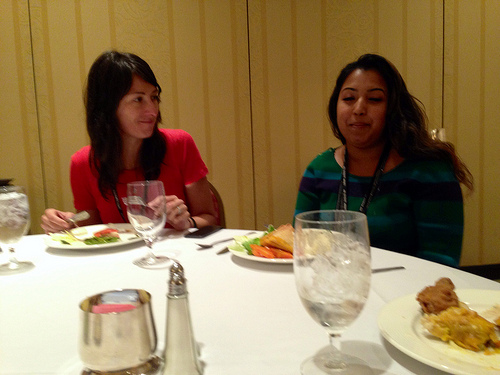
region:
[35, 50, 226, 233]
a woman in a red shirt sitting at a table.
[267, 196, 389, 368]
a glass filled with ice and liquid.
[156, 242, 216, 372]
a very tall salt shaker.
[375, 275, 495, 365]
a white plate with food on it.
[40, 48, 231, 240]
a woman sitting at a table.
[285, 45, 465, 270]
a woman sitting at a table with a plate.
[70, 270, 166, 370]
a metal container filled with sweetener.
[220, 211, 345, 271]
a plate topped with food.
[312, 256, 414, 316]
a metal eating utensil.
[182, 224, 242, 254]
a metal spoon on a table.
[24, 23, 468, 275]
Two women dining at a table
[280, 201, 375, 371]
Clear glass with ice in it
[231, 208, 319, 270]
A plate of food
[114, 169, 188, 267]
An empty glass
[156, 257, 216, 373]
A tall glass salt shaker with a silver top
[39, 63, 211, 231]
Woman holding knife and fork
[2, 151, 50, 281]
Glass full of ice water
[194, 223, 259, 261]
Utensils on the table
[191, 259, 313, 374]
Solid white table cloth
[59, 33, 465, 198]
Two women with long, dark hair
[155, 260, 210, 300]
silver top on salt shaker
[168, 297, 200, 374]
bottom part of salt shaker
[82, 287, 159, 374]
silver sugar container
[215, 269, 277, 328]
part of the dining table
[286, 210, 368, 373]
a transparent drinking blass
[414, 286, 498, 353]
some food on plate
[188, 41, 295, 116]
part of the wall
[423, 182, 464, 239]
part of top on woman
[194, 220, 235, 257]
silverware on the table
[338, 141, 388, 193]
part of neck strap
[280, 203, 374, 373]
glass of water with ice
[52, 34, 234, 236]
woman in a red shirt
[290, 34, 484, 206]
women in a blue and green shirt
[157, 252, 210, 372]
salt shaker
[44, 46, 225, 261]
woman eating a meal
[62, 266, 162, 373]
silver sugar holder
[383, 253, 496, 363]
dinner plate with chicken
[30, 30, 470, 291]
two woman seated at a table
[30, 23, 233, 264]
woman with dark hair and bangs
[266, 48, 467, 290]
woman in a striped shirt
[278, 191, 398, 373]
a glass of water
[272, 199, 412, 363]
a tall glass of water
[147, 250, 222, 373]
a salt dispernser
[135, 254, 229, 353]
a full salt dispenser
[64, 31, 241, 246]
a women with red shirt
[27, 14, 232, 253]
a person with red shirt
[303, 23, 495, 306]
a person with long hair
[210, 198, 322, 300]
a plate of food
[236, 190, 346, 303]
a white plate of food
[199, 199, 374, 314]
food on a plate